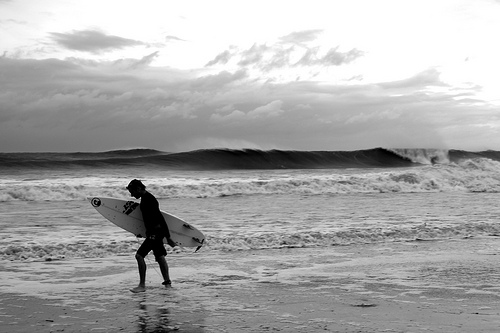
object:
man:
[126, 177, 178, 295]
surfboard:
[85, 195, 206, 253]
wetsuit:
[133, 193, 169, 259]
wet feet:
[128, 284, 149, 294]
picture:
[2, 5, 498, 332]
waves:
[0, 215, 499, 263]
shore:
[0, 262, 499, 333]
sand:
[0, 284, 498, 333]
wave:
[372, 146, 450, 167]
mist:
[0, 39, 499, 153]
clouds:
[0, 0, 499, 151]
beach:
[0, 266, 499, 333]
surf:
[0, 158, 499, 264]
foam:
[3, 172, 497, 203]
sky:
[0, 0, 499, 150]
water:
[0, 144, 498, 330]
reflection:
[126, 301, 175, 332]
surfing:
[85, 175, 205, 293]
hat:
[124, 178, 144, 191]